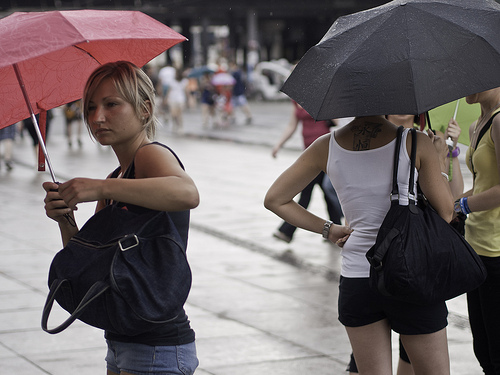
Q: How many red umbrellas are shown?
A: One.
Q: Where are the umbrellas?
A: In people's hands.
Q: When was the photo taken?
A: Daytime.